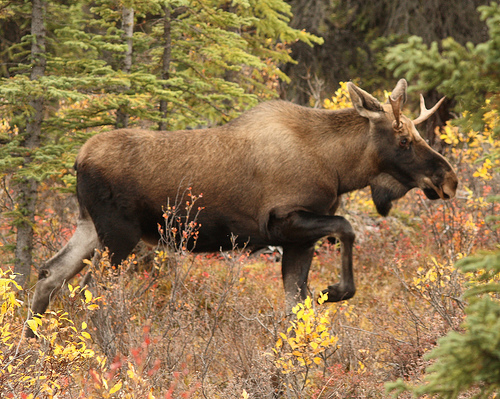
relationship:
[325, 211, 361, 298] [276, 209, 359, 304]
joints on leg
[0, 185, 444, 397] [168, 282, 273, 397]
leaves among bare branches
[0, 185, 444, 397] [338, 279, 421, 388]
leaves among bare branches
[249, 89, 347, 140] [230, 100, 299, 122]
hump on hump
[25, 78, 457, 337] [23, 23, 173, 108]
elk in forest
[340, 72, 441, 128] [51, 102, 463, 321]
horns on moose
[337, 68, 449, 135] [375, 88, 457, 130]
elk has antlers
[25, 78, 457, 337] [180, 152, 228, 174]
elk with fur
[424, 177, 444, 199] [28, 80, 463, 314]
mouth on a moose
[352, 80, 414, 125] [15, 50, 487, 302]
ears on a moose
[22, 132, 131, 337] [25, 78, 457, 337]
hindquarters of a elk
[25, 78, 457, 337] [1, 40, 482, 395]
elk in area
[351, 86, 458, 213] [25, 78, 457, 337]
head of elk